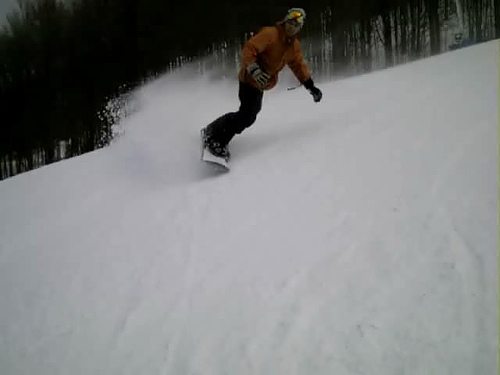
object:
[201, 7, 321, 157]
person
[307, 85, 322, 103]
glove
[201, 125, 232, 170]
snowboard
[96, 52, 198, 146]
snow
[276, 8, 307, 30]
hat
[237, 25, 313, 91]
jacket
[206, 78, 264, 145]
pants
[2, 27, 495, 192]
hill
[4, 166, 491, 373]
track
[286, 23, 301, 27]
goggles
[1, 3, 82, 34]
sky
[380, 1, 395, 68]
tree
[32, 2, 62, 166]
tree